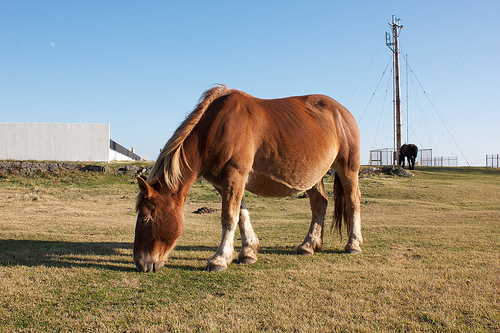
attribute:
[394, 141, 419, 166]
cow — wild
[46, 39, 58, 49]
moon — small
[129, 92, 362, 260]
horse — brown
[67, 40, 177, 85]
sky — clear, blue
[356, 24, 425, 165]
pole — tall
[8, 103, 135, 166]
building — white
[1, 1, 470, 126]
sky — clear, blue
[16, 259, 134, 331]
grass — green